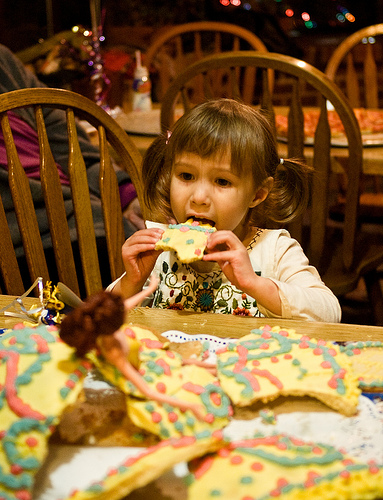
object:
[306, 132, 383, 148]
platter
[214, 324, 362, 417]
cookie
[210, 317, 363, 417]
cookie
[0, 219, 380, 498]
cookie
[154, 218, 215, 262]
food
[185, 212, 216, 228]
mouth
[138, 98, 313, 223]
hair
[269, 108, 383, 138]
pizza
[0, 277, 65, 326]
ribbon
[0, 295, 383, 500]
table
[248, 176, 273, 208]
left ear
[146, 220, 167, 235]
raspberry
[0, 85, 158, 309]
chair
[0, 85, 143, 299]
slat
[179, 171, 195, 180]
eyes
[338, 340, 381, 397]
cookie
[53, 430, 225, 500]
cookie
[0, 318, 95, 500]
cookie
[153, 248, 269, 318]
design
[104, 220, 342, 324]
shirt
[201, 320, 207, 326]
crumbs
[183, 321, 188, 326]
crumbs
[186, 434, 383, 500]
cookies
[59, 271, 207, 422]
doll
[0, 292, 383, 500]
cloth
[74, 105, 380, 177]
table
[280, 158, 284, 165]
ties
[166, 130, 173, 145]
ties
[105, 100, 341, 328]
girl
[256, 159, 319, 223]
pig tail